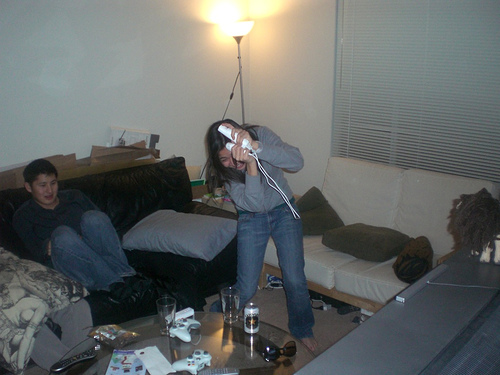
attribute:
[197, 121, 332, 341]
girl — playing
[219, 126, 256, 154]
wii controller — nintendo, White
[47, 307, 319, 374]
table — glass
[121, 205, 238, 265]
white pillow — fluffy, long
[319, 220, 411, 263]
pillow — brown, square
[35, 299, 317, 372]
table — glass, circular, coffee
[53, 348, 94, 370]
remote — controller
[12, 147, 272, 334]
couch — black, leather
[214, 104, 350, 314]
woman — playing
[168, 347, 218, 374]
controller — gaming, white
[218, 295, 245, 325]
glass — drinking, empty, tall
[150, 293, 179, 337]
glass — empty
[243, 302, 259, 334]
can — drink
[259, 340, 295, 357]
sunglasses — dark, black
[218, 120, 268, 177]
wii controller — white